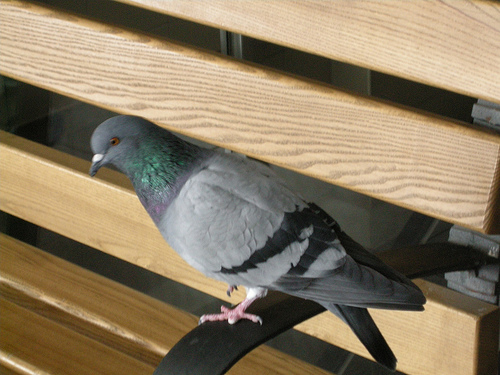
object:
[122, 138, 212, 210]
tint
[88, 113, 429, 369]
dove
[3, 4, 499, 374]
bench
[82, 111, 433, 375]
left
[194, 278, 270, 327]
left leg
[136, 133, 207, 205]
neck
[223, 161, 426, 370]
wings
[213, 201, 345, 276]
black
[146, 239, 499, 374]
armrest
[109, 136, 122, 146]
eye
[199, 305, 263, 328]
pink foot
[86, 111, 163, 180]
head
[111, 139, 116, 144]
black pupil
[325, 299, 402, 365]
tail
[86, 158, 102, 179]
beak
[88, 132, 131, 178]
face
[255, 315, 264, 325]
toenail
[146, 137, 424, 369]
feathers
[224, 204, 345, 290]
stripes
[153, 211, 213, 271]
breast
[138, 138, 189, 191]
green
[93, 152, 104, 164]
spot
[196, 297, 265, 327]
feet